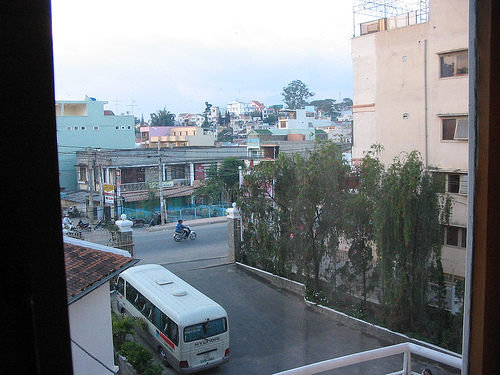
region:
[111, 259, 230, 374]
A bus in the photo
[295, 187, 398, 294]
Trees in the picture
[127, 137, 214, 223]
Buildings in the photo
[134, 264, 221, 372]
A white van on the parking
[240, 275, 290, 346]
Road with tarmac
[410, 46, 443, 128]
A buiding in the picture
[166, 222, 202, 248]
A motorbike on the road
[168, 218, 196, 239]
A person riding a bike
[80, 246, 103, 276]
Brick roofing on the building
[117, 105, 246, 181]
Buidings in the city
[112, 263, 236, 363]
the bus is parked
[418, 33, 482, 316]
windows of the building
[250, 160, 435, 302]
trees next to building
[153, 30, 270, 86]
the sky is hazy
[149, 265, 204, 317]
roof of the bus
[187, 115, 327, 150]
buildings in the distance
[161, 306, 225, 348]
window on the bus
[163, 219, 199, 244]
bicyclist on the road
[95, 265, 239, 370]
this is a bus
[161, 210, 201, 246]
this is a man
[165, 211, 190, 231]
this is a man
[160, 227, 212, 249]
this is a bike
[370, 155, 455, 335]
this is a tree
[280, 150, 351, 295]
this is a tree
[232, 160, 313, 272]
this is a tree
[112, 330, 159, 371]
this is a tree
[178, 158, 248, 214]
this is a tree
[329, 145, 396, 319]
this is a tree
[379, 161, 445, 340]
this is a tree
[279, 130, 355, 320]
this is a tree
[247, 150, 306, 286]
this is a tree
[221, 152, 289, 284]
this is a tree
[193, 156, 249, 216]
this is a tree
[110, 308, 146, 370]
this is a tree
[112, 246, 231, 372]
this is a bus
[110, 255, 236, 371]
A white city bus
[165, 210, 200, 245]
A person riding a motorbike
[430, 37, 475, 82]
A window on a building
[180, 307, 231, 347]
Back window of a bus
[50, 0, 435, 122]
The sky appears overcast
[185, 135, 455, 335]
Green leaves on the trees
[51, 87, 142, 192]
A large blue building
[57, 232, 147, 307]
The roof of a building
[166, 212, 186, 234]
A person wearing a blue coat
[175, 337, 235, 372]
Two red rear bus lights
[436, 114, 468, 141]
A window on a building.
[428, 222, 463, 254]
A window on a building.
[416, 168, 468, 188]
A window on a building.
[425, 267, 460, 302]
A window on a building.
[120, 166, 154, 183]
A window on a building.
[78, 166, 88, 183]
A window on a building.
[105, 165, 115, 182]
A window on a building.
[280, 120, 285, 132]
A window on a building.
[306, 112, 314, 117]
A window on a building.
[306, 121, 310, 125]
A window on a building.